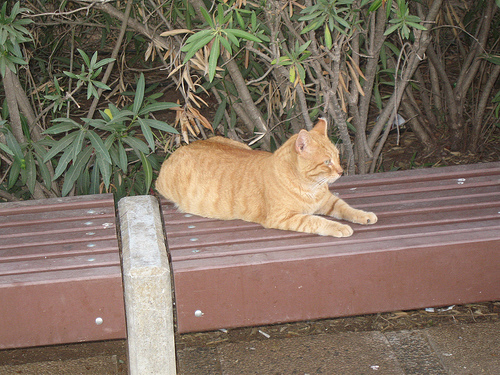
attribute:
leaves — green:
[170, 23, 270, 82]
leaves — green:
[175, 7, 275, 81]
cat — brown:
[146, 112, 382, 242]